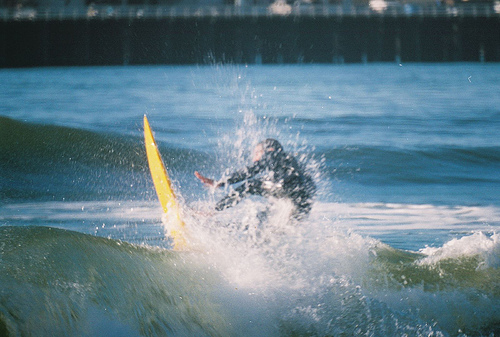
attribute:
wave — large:
[0, 225, 497, 335]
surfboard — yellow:
[143, 112, 191, 242]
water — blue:
[2, 61, 498, 335]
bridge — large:
[0, 2, 498, 63]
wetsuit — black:
[212, 143, 321, 217]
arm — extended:
[221, 150, 276, 190]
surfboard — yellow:
[139, 109, 181, 238]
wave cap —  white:
[416, 230, 498, 271]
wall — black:
[0, 12, 497, 67]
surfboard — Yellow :
[137, 109, 222, 275]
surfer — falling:
[193, 137, 327, 252]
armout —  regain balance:
[175, 122, 318, 222]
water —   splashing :
[176, 203, 337, 332]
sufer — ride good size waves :
[140, 73, 339, 250]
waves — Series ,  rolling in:
[25, 73, 138, 181]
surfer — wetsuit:
[205, 126, 356, 269]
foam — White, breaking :
[198, 200, 318, 285]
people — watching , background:
[206, 126, 307, 258]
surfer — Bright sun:
[192, 109, 336, 276]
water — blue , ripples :
[181, 60, 451, 140]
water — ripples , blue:
[136, 60, 395, 127]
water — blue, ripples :
[66, 46, 375, 121]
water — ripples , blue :
[64, 60, 401, 117]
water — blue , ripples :
[30, 32, 423, 149]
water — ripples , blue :
[52, 59, 396, 142]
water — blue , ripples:
[63, 62, 373, 125]